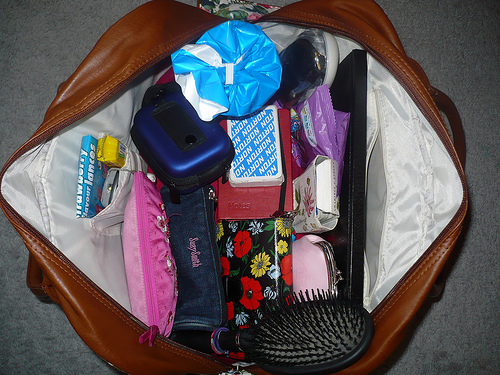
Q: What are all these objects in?
A: Brown bag.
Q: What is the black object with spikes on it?
A: Hairbrush.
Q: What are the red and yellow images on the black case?
A: Flowers.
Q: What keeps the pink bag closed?
A: Zipper.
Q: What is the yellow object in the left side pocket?
A: Chewing gum.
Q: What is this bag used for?
A: Travel.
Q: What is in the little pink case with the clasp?
A: Coins.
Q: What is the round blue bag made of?
A: Plastic.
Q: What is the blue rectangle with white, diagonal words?
A: Playing cards.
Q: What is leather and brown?
A: The bag.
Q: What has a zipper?
A: Brown bag.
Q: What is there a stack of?
A: Cards.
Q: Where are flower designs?
A: On a wallet.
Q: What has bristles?
A: Hairbrush.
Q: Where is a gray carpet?
A: On the floor.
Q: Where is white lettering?
A: On playing cards.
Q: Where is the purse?
A: On the floor.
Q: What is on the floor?
A: A blue carpet.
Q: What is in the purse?
A: A brush.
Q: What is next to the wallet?
A: A pouch.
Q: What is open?
A: A bag.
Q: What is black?
A: Hair Brush.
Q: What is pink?
A: Small bag.